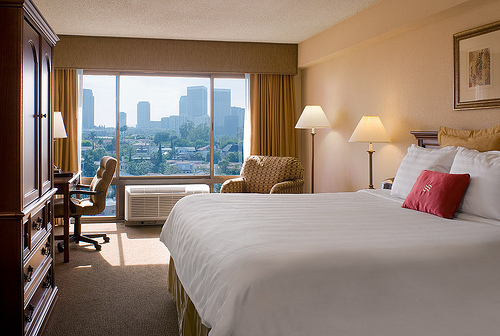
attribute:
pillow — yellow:
[432, 126, 499, 154]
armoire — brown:
[2, 0, 63, 333]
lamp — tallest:
[291, 102, 331, 192]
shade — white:
[347, 113, 394, 147]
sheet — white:
[159, 190, 499, 334]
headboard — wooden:
[409, 129, 444, 151]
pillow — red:
[403, 168, 470, 220]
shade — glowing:
[348, 115, 392, 145]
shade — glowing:
[295, 104, 335, 133]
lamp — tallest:
[295, 104, 334, 196]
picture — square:
[467, 47, 495, 86]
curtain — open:
[52, 67, 80, 178]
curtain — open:
[248, 73, 303, 157]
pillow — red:
[412, 160, 473, 251]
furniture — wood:
[12, 215, 69, 311]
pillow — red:
[393, 168, 466, 219]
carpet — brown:
[73, 288, 127, 323]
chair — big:
[230, 148, 326, 224]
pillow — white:
[470, 151, 494, 219]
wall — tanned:
[370, 67, 412, 110]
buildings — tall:
[150, 106, 201, 146]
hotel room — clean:
[13, 3, 499, 332]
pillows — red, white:
[390, 132, 499, 220]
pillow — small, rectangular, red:
[399, 166, 474, 223]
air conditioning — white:
[113, 178, 214, 230]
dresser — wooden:
[1, 5, 61, 334]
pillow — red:
[401, 158, 474, 223]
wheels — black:
[43, 230, 119, 261]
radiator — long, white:
[120, 180, 215, 226]